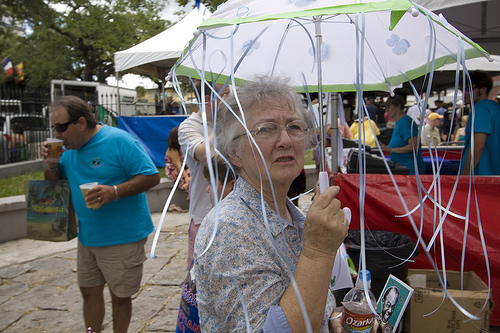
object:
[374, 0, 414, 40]
ribbon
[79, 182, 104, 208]
beers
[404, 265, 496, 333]
box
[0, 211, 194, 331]
ground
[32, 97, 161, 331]
man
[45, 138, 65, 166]
beer cup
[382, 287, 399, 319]
man's head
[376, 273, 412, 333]
sign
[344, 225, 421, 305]
trash can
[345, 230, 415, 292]
trash bag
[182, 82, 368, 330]
woman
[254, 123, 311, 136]
eyeglasses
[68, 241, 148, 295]
shorts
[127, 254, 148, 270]
flap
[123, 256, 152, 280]
pocket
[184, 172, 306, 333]
shirt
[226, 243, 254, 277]
flowers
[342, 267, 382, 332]
bottle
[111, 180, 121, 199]
bracelet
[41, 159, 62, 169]
wrist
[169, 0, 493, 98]
umbrella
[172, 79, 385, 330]
female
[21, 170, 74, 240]
bag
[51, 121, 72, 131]
sunglasses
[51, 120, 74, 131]
glasses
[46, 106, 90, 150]
face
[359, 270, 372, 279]
cap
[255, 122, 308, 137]
glasses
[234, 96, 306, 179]
face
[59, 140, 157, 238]
shirt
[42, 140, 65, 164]
cup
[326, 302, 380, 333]
hands